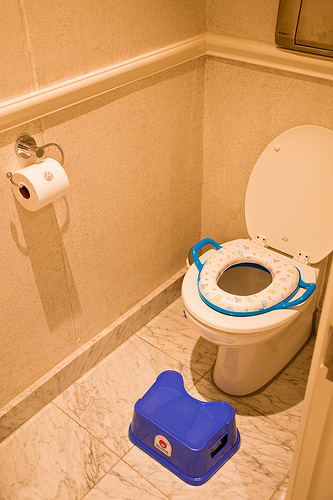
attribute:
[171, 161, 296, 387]
toilet — white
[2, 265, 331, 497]
tiles — square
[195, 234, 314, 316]
seat — white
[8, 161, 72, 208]
toilet paper — white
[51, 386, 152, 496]
tile — brown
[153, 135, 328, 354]
toilet — toddler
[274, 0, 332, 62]
holder — white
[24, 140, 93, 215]
holder — white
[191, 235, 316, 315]
training seat — white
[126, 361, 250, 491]
potty step — blue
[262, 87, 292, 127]
ground — white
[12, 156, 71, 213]
paper — white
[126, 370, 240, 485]
stool — white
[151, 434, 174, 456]
sticker — brown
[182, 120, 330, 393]
toilet — white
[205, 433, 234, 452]
handle — white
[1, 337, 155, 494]
tile — white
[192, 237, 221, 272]
seat handle — blue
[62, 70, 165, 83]
molding — white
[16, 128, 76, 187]
dispenser — metal